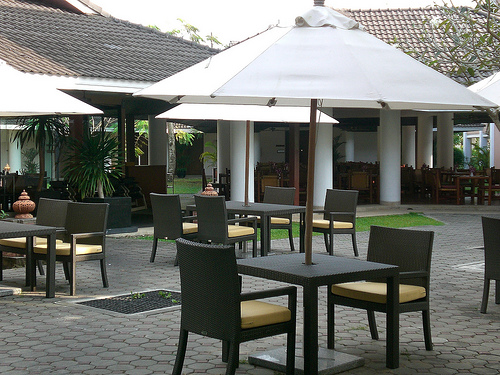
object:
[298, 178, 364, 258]
chair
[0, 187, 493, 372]
patio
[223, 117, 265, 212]
pillar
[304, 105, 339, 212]
pillar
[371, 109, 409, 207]
pillar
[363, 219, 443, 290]
back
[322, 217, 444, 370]
chair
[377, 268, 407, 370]
legs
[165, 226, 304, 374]
chair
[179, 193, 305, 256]
table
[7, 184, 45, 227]
urn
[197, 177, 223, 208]
urn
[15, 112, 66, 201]
trees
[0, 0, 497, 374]
cafe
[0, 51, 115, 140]
umbrella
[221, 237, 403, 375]
table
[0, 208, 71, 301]
table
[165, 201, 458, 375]
two chairs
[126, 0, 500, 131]
roof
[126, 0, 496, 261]
umbrella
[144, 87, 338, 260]
umbrella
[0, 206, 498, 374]
floor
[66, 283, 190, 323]
vent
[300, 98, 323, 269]
pole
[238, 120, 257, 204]
pole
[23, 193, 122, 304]
chair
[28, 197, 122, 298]
chair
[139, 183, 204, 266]
chair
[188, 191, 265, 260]
chair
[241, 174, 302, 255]
chair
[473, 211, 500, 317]
chair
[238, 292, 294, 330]
cushion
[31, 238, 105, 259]
cushion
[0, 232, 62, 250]
cushion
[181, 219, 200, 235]
cushion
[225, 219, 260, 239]
cushion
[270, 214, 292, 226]
cushion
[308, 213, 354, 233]
cushion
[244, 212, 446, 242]
grass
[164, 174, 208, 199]
grass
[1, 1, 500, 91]
roof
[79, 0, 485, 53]
sky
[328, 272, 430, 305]
cushion